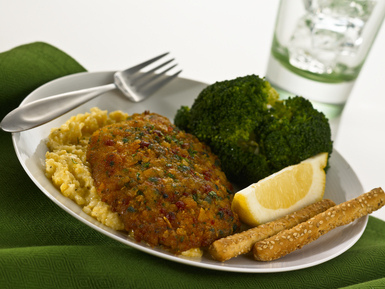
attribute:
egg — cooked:
[37, 106, 151, 233]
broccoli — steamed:
[163, 71, 340, 187]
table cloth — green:
[0, 39, 372, 286]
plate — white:
[8, 67, 367, 274]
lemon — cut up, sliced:
[228, 151, 333, 229]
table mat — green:
[1, 39, 372, 286]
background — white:
[1, 0, 371, 118]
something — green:
[173, 74, 336, 194]